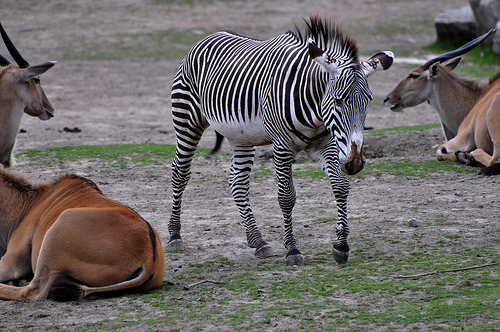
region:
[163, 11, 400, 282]
a zebra walking in a field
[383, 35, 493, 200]
a giselle laying on the ground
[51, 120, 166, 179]
a patch of green grass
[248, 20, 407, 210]
a zebra with a red nose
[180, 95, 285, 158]
a zebra with a white stomach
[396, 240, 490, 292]
a tree branch on the ground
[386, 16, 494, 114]
horns on top of a giselles head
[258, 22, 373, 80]
the maine on a zebra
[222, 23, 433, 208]
a zebra with its head down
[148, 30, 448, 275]
a zebra walking with its head down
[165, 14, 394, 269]
one zebra with black and white stripes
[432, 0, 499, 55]
two large grey and black rocks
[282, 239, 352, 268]
two front hooves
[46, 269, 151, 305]
brown tail with bushy black end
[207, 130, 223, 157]
black end of a zebra's tail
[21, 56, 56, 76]
one black ear with white tip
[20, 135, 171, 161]
one patch of green grass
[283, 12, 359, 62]
one tuft of black and white neck hair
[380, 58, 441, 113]
left side of a gazelle's face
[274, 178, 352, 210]
two knobby front knees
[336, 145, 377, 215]
Zebra has black nose.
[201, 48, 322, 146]
Zebra is black and white.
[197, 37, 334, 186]
Zebra has many stripes.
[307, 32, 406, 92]
Zebra has black and white mane.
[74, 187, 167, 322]
Brown animal sitting down near zebra.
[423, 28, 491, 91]
Large black horns on animal.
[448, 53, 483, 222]
Large brown animal laying in grass.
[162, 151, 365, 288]
Zebra walking thru grassy area.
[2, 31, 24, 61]
Large horns on animal's head.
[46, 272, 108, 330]
Animal has black hair on the tip of tail.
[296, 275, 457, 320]
the grass is dry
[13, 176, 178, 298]
the animal is brown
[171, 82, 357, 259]
the zebra is black and white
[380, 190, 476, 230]
there are grey patches on ground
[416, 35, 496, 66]
the horns are grey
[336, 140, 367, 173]
the nose is brown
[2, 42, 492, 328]
the scene is in the wild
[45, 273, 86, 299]
the tip of tail is black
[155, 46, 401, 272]
the zebra has four legs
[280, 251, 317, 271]
the hoofs are grey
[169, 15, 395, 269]
a black and white zebra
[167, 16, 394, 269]
a zebra with black and white stripes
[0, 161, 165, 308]
a gazelle laying down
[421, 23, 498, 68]
black horns of gazelle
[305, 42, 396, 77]
black and white zebra ears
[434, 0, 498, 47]
gray rocks in background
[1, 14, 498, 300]
a group of animals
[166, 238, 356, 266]
hooves of zebra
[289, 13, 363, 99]
a bushy zebra mane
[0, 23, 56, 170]
a gazelle looking away